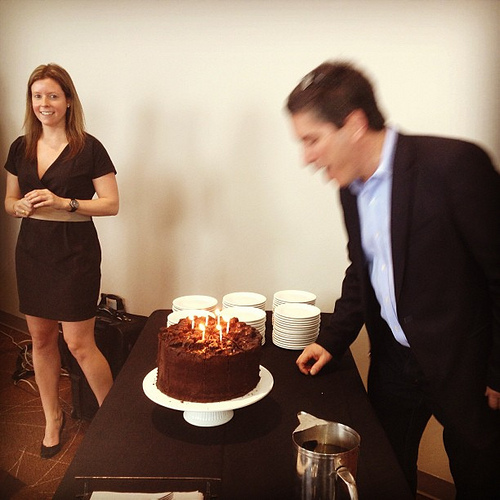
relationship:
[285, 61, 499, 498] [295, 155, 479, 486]
man in suit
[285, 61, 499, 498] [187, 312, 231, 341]
man blowing candles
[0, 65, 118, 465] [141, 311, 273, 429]
woman looking at cake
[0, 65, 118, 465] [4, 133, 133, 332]
woman with dress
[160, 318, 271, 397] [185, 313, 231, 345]
cake with candles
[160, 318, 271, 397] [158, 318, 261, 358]
cake with sprinkles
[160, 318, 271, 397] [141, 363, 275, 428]
cake on dish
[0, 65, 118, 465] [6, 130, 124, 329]
woman in dress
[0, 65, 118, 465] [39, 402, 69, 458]
woman in pumps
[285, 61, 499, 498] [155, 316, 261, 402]
man blowing at cake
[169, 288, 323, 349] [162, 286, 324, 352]
stacks of plate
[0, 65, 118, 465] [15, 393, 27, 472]
woman standing on floor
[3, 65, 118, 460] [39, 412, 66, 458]
woman wearing pumps